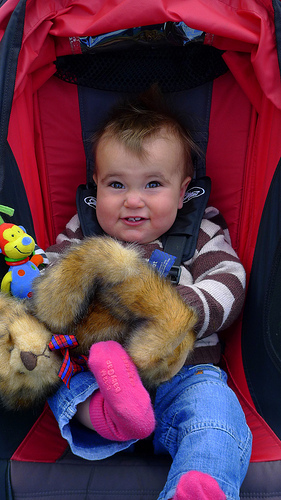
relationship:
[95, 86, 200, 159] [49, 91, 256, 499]
hair on baby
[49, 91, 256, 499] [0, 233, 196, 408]
baby holding bear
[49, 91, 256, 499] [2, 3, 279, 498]
baby in stroller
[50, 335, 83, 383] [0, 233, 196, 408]
ribbon on bear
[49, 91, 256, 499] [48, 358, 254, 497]
baby in jeans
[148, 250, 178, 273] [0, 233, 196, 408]
tag on bear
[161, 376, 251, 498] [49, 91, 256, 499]
leg of baby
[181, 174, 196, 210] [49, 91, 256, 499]
ear of baby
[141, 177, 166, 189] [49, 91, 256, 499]
eye of baby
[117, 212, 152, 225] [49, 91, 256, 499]
mouth of baby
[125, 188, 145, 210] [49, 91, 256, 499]
nose of baby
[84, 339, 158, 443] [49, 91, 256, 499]
sock on baby